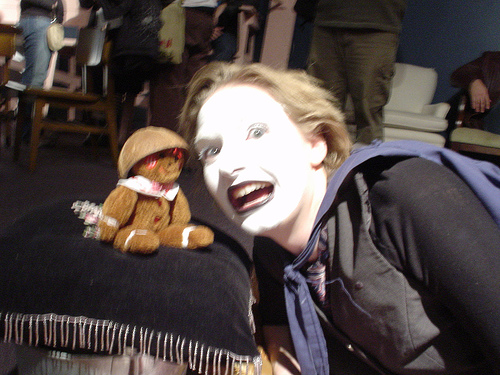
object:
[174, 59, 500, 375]
woman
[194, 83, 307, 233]
makeup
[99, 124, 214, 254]
bear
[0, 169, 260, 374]
pillow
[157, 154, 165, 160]
eyes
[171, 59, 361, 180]
hair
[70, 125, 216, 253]
teddy bear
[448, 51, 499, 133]
people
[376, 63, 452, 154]
chair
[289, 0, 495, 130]
wall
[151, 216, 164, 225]
buttons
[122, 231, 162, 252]
feet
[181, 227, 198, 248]
lines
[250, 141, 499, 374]
shirt